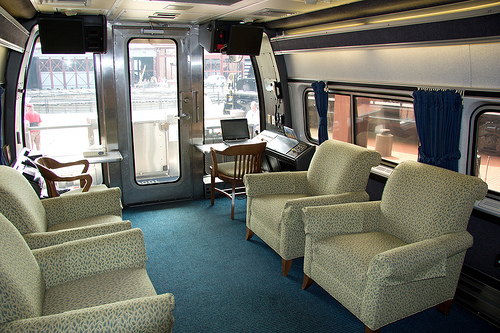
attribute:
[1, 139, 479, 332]
room has chair — specked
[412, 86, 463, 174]
curtain is hanging — blue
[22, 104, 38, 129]
shirt — red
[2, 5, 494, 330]
bus — remodeled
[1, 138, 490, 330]
chairs — blue, spotted, yellowy, chintzish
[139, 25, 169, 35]
tube — pneumatic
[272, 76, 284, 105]
telephone — old, landline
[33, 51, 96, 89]
fence — fancy, red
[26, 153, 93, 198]
chair — brown, wood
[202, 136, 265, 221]
chair — brown, wood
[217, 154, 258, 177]
pillow — white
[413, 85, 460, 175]
curtain — blue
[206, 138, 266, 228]
chair — brown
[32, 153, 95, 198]
chair — brown, wooden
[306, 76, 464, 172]
curtains — blue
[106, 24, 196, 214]
door — metal, glass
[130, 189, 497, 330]
carpeting — blue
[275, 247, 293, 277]
chair leg — wooden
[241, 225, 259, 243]
chair leg — wooden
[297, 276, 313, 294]
chair leg — wooden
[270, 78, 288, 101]
phone — black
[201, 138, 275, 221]
chair — wooden, brown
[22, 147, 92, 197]
chair — wooden